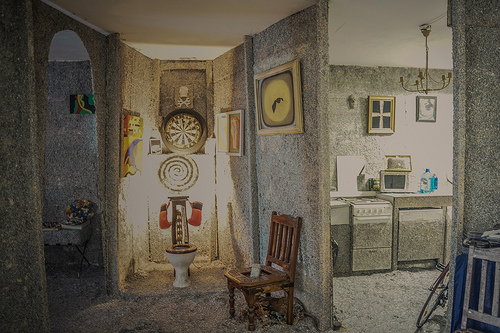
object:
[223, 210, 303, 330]
chair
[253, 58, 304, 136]
picture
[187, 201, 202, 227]
glove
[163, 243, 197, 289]
toilet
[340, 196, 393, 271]
stove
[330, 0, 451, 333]
kitchen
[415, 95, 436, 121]
picture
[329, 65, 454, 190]
wall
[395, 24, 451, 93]
light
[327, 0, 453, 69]
ceiling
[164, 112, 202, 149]
dart board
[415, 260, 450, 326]
bike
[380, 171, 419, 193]
microwave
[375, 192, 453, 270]
counter